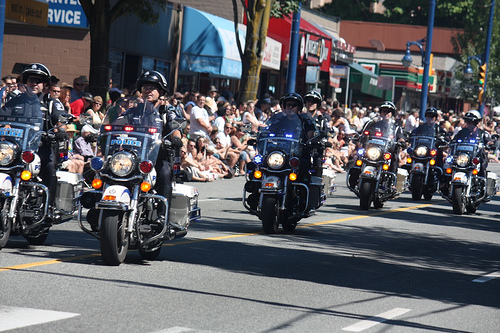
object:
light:
[140, 181, 152, 192]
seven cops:
[3, 61, 500, 267]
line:
[0, 199, 452, 273]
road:
[6, 161, 500, 333]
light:
[138, 159, 154, 174]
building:
[92, 0, 283, 111]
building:
[241, 0, 336, 109]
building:
[296, 4, 359, 109]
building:
[338, 18, 485, 118]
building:
[0, 0, 99, 101]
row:
[0, 0, 500, 115]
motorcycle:
[240, 107, 336, 236]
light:
[265, 150, 286, 171]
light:
[288, 172, 298, 181]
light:
[355, 159, 363, 167]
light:
[446, 167, 453, 174]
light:
[406, 157, 412, 164]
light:
[91, 178, 103, 190]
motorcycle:
[340, 116, 411, 210]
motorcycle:
[400, 115, 456, 202]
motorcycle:
[434, 122, 500, 216]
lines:
[339, 306, 414, 332]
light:
[89, 156, 105, 172]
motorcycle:
[69, 95, 204, 268]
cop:
[347, 99, 408, 192]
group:
[0, 56, 500, 268]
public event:
[0, 0, 500, 333]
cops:
[244, 91, 328, 216]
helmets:
[377, 98, 399, 118]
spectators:
[79, 95, 108, 157]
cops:
[79, 69, 190, 232]